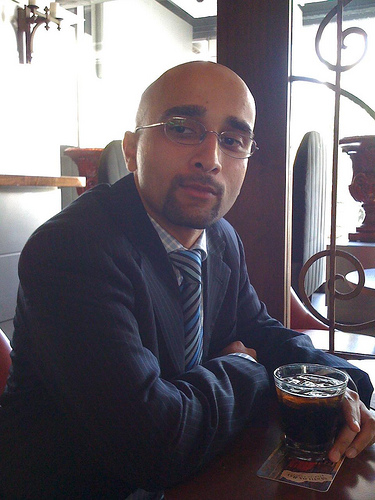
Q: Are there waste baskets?
A: No, there are no waste baskets.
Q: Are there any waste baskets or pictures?
A: No, there are no waste baskets or pictures.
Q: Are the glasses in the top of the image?
A: Yes, the glasses are in the top of the image.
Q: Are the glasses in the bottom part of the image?
A: No, the glasses are in the top of the image.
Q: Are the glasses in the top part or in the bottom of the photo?
A: The glasses are in the top of the image.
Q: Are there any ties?
A: Yes, there is a tie.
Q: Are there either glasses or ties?
A: Yes, there is a tie.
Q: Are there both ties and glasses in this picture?
A: Yes, there are both a tie and glasses.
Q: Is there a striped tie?
A: Yes, there is a striped tie.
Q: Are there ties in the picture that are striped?
A: Yes, there is a tie that is striped.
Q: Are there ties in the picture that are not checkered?
A: Yes, there is a striped tie.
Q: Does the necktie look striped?
A: Yes, the necktie is striped.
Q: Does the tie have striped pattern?
A: Yes, the tie is striped.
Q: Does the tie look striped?
A: Yes, the tie is striped.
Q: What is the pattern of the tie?
A: The tie is striped.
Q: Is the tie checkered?
A: No, the tie is striped.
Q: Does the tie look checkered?
A: No, the tie is striped.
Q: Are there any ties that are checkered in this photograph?
A: No, there is a tie but it is striped.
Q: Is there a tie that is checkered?
A: No, there is a tie but it is striped.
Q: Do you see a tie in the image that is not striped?
A: No, there is a tie but it is striped.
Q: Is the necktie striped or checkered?
A: The necktie is striped.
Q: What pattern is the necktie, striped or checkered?
A: The necktie is striped.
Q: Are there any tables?
A: Yes, there is a table.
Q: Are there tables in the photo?
A: Yes, there is a table.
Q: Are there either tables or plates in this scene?
A: Yes, there is a table.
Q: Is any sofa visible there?
A: No, there are no sofas.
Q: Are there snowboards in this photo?
A: No, there are no snowboards.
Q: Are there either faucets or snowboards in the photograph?
A: No, there are no snowboards or faucets.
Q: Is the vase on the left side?
A: Yes, the vase is on the left of the image.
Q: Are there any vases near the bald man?
A: Yes, there is a vase near the man.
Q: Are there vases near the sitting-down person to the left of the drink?
A: Yes, there is a vase near the man.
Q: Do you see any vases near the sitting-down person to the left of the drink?
A: Yes, there is a vase near the man.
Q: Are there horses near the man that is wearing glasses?
A: No, there is a vase near the man.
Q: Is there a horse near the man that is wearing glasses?
A: No, there is a vase near the man.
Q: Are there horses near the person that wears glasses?
A: No, there is a vase near the man.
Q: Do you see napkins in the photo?
A: No, there are no napkins.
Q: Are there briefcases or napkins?
A: No, there are no napkins or briefcases.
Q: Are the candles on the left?
A: Yes, the candles are on the left of the image.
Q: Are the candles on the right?
A: No, the candles are on the left of the image.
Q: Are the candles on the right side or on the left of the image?
A: The candles are on the left of the image.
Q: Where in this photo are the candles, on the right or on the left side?
A: The candles are on the left of the image.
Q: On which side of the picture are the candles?
A: The candles are on the left of the image.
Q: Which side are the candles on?
A: The candles are on the left of the image.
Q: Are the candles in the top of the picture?
A: Yes, the candles are in the top of the image.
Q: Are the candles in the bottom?
A: No, the candles are in the top of the image.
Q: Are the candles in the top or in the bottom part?
A: The candles are in the top of the image.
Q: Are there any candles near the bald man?
A: Yes, there are candles near the man.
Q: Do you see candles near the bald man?
A: Yes, there are candles near the man.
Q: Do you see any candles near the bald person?
A: Yes, there are candles near the man.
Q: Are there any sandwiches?
A: No, there are no sandwiches.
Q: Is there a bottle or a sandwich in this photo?
A: No, there are no sandwiches or bottles.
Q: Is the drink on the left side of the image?
A: No, the drink is on the right of the image.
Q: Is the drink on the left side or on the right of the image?
A: The drink is on the right of the image.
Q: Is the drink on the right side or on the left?
A: The drink is on the right of the image.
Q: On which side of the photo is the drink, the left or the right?
A: The drink is on the right of the image.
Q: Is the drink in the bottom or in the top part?
A: The drink is in the bottom of the image.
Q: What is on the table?
A: The drink is on the table.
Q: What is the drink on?
A: The drink is on the table.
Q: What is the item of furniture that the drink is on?
A: The piece of furniture is a table.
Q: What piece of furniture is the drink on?
A: The drink is on the table.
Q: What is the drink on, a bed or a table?
A: The drink is on a table.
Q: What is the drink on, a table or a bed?
A: The drink is on a table.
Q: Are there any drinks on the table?
A: Yes, there is a drink on the table.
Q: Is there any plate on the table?
A: No, there is a drink on the table.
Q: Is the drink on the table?
A: Yes, the drink is on the table.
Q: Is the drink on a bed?
A: No, the drink is on the table.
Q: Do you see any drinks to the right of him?
A: Yes, there is a drink to the right of the man.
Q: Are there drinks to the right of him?
A: Yes, there is a drink to the right of the man.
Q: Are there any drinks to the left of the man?
A: No, the drink is to the right of the man.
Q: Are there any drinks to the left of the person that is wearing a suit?
A: No, the drink is to the right of the man.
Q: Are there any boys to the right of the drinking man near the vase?
A: No, there is a drink to the right of the man.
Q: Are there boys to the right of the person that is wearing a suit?
A: No, there is a drink to the right of the man.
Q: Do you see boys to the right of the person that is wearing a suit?
A: No, there is a drink to the right of the man.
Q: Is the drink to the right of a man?
A: Yes, the drink is to the right of a man.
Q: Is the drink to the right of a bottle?
A: No, the drink is to the right of a man.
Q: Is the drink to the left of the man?
A: No, the drink is to the right of the man.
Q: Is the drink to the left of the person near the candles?
A: No, the drink is to the right of the man.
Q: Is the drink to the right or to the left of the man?
A: The drink is to the right of the man.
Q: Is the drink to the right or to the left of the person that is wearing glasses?
A: The drink is to the right of the man.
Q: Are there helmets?
A: No, there are no helmets.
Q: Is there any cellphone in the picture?
A: No, there are no cell phones.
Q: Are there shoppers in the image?
A: No, there are no shoppers.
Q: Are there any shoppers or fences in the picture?
A: No, there are no shoppers or fences.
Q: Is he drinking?
A: Yes, the man is drinking.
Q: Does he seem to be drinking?
A: Yes, the man is drinking.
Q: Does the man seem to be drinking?
A: Yes, the man is drinking.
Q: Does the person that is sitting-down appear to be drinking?
A: Yes, the man is drinking.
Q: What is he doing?
A: The man is drinking.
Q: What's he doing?
A: The man is drinking.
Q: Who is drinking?
A: The man is drinking.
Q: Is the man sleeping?
A: No, the man is drinking.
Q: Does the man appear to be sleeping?
A: No, the man is drinking.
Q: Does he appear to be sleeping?
A: No, the man is drinking.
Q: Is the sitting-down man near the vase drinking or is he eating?
A: The man is drinking.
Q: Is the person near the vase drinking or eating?
A: The man is drinking.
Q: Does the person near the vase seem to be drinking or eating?
A: The man is drinking.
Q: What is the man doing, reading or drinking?
A: The man is drinking.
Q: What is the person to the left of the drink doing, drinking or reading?
A: The man is drinking.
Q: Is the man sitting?
A: Yes, the man is sitting.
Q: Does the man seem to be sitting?
A: Yes, the man is sitting.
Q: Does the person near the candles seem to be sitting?
A: Yes, the man is sitting.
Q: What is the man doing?
A: The man is sitting.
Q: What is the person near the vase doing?
A: The man is sitting.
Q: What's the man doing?
A: The man is sitting.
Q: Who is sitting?
A: The man is sitting.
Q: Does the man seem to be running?
A: No, the man is sitting.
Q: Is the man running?
A: No, the man is sitting.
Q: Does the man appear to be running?
A: No, the man is sitting.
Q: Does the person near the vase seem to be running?
A: No, the man is sitting.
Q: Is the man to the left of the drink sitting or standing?
A: The man is sitting.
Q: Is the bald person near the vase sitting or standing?
A: The man is sitting.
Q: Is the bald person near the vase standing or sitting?
A: The man is sitting.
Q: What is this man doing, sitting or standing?
A: The man is sitting.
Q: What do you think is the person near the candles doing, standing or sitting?
A: The man is sitting.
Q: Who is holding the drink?
A: The man is holding the drink.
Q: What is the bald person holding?
A: The man is holding the drink.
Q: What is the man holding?
A: The man is holding the drink.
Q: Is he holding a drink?
A: Yes, the man is holding a drink.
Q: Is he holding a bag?
A: No, the man is holding a drink.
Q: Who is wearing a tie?
A: The man is wearing a tie.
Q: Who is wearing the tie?
A: The man is wearing a tie.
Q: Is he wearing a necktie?
A: Yes, the man is wearing a necktie.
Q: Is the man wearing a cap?
A: No, the man is wearing a necktie.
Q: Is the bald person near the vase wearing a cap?
A: No, the man is wearing a necktie.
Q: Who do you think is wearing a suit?
A: The man is wearing a suit.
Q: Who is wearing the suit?
A: The man is wearing a suit.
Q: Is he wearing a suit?
A: Yes, the man is wearing a suit.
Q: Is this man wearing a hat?
A: No, the man is wearing a suit.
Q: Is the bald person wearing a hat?
A: No, the man is wearing a suit.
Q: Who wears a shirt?
A: The man wears a shirt.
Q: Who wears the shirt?
A: The man wears a shirt.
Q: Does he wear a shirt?
A: Yes, the man wears a shirt.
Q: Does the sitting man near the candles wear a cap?
A: No, the man wears a shirt.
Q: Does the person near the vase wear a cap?
A: No, the man wears a shirt.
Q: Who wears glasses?
A: The man wears glasses.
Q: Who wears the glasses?
A: The man wears glasses.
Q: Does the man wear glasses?
A: Yes, the man wears glasses.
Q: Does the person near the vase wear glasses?
A: Yes, the man wears glasses.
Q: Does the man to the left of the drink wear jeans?
A: No, the man wears glasses.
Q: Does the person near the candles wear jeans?
A: No, the man wears glasses.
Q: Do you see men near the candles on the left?
A: Yes, there is a man near the candles.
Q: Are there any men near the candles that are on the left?
A: Yes, there is a man near the candles.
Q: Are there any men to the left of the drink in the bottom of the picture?
A: Yes, there is a man to the left of the drink.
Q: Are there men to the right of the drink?
A: No, the man is to the left of the drink.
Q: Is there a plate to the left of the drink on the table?
A: No, there is a man to the left of the drink.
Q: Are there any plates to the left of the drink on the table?
A: No, there is a man to the left of the drink.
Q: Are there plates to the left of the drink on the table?
A: No, there is a man to the left of the drink.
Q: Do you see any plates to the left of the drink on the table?
A: No, there is a man to the left of the drink.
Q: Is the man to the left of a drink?
A: Yes, the man is to the left of a drink.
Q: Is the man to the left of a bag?
A: No, the man is to the left of a drink.